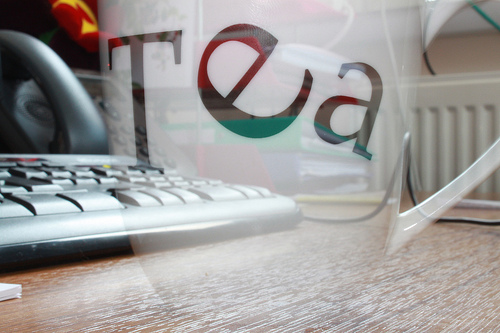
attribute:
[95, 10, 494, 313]
glare —  light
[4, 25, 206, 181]
phone —  black 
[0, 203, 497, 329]
desk — wooden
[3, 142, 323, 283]
computer keyboard —  Black and gray,  computer's 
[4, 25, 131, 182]
telephone —  Black,  corded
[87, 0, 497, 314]
tea cup —  Faded ,  white ,  for tea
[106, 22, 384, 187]
letters —  Black,  TEA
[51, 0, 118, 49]
object — orange, yellow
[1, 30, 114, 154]
phone — black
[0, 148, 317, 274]
keyboard —  silver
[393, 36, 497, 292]
cup —  White , with handle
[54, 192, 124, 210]
button —  Three,  black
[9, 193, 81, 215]
button —  black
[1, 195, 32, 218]
button —  black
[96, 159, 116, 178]
dot — yellow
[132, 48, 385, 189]
mug — white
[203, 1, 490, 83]
moulding —  white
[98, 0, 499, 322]
teacup —  white,  partially transparent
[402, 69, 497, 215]
ac vent —  White,  AC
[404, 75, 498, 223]
vent — white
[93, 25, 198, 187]
letter —  T,  capitalized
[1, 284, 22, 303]
papers — white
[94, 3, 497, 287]
mug — white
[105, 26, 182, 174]
letter —  Black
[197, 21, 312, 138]
letter — black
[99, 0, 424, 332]
faded cup —  white,  faded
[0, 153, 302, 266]
keyboard — black, plastic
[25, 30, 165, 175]
phone — black